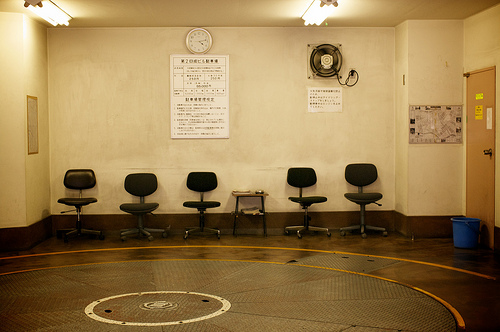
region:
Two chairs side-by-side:
[282, 160, 388, 237]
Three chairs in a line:
[58, 165, 222, 250]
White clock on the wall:
[183, 25, 214, 57]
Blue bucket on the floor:
[448, 211, 488, 252]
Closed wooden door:
[463, 66, 496, 225]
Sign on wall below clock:
[168, 53, 230, 138]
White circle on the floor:
[82, 282, 231, 327]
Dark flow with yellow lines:
[0, 237, 498, 329]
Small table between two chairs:
[226, 186, 269, 243]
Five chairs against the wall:
[53, 159, 386, 249]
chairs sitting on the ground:
[51, 150, 418, 255]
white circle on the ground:
[70, 268, 242, 324]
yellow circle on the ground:
[9, 221, 487, 328]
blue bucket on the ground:
[437, 192, 487, 265]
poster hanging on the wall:
[134, 42, 254, 147]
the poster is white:
[156, 52, 277, 167]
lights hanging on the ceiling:
[18, 0, 105, 54]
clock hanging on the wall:
[178, 19, 223, 61]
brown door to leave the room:
[454, 55, 499, 237]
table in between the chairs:
[221, 175, 291, 255]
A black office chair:
[55, 166, 105, 243]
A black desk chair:
[118, 170, 169, 242]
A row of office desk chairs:
[58, 163, 395, 240]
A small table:
[228, 187, 271, 238]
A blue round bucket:
[447, 215, 482, 250]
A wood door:
[462, 68, 496, 250]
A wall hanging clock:
[184, 25, 212, 55]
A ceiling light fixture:
[299, 1, 338, 27]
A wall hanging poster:
[168, 53, 230, 140]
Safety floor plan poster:
[405, 101, 466, 146]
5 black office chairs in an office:
[20, 121, 415, 267]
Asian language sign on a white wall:
[129, 55, 245, 145]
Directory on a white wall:
[388, 77, 469, 164]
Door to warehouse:
[361, 67, 493, 321]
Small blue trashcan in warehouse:
[440, 187, 485, 277]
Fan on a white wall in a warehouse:
[266, 20, 365, 93]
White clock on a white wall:
[167, 15, 240, 54]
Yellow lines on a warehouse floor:
[35, 224, 459, 276]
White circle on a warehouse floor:
[42, 209, 334, 327]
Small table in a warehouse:
[218, 157, 289, 299]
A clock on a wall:
[173, 20, 226, 57]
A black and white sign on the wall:
[300, 81, 352, 116]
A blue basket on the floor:
[444, 207, 487, 255]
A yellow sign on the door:
[467, 87, 488, 105]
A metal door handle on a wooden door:
[477, 142, 496, 161]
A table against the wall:
[226, 181, 275, 246]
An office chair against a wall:
[335, 156, 390, 248]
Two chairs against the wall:
[276, 157, 389, 245]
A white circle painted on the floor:
[76, 273, 241, 329]